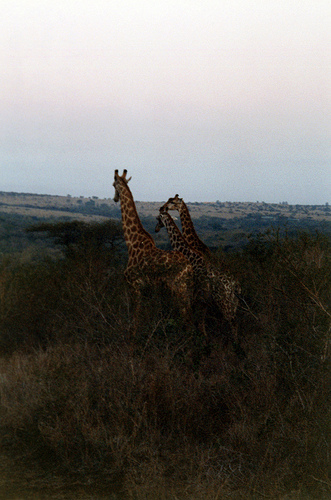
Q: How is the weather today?
A: It is clear.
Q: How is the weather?
A: It is clear.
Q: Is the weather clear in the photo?
A: Yes, it is clear.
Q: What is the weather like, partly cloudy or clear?
A: It is clear.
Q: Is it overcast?
A: No, it is clear.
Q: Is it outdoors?
A: Yes, it is outdoors.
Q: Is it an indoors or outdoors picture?
A: It is outdoors.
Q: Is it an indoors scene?
A: No, it is outdoors.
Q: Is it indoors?
A: No, it is outdoors.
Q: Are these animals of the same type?
A: Yes, all the animals are giraffes.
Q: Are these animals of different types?
A: No, all the animals are giraffes.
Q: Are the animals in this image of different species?
A: No, all the animals are giraffes.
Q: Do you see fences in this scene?
A: No, there are no fences.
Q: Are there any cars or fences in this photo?
A: No, there are no fences or cars.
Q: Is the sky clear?
A: Yes, the sky is clear.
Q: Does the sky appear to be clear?
A: Yes, the sky is clear.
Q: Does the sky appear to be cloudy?
A: No, the sky is clear.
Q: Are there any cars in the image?
A: No, there are no cars.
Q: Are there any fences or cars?
A: No, there are no cars or fences.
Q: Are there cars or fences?
A: No, there are no cars or fences.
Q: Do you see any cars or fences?
A: No, there are no cars or fences.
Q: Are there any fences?
A: No, there are no fences.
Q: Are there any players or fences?
A: No, there are no fences or players.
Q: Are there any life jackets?
A: No, there are no life jackets.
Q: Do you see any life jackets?
A: No, there are no life jackets.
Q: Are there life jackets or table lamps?
A: No, there are no life jackets or table lamps.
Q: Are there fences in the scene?
A: No, there are no fences.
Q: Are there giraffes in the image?
A: Yes, there is a giraffe.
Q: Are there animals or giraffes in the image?
A: Yes, there is a giraffe.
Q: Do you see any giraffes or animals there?
A: Yes, there is a giraffe.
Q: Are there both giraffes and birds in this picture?
A: No, there is a giraffe but no birds.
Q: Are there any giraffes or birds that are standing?
A: Yes, the giraffe is standing.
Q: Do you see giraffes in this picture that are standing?
A: Yes, there is a giraffe that is standing.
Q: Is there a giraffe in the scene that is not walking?
A: Yes, there is a giraffe that is standing.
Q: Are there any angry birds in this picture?
A: No, there are no angry birds.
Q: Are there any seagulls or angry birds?
A: No, there are no angry birds or seagulls.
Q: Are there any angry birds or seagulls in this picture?
A: No, there are no angry birds or seagulls.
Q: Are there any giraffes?
A: Yes, there is a giraffe.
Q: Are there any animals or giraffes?
A: Yes, there is a giraffe.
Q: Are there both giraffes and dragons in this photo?
A: No, there is a giraffe but no dragons.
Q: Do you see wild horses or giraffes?
A: Yes, there is a wild giraffe.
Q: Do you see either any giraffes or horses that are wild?
A: Yes, the giraffe is wild.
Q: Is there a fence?
A: No, there are no fences.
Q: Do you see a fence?
A: No, there are no fences.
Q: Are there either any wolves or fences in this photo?
A: No, there are no fences or wolves.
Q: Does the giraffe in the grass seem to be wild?
A: Yes, the giraffe is wild.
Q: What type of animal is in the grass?
A: The animal is a giraffe.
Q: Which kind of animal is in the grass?
A: The animal is a giraffe.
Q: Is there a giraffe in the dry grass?
A: Yes, there is a giraffe in the grass.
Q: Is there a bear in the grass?
A: No, there is a giraffe in the grass.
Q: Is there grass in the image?
A: Yes, there is grass.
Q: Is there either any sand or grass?
A: Yes, there is grass.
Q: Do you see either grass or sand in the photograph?
A: Yes, there is grass.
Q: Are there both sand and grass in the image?
A: No, there is grass but no sand.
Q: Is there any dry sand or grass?
A: Yes, there is dry grass.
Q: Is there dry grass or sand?
A: Yes, there is dry grass.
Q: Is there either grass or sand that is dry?
A: Yes, the grass is dry.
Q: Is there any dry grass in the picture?
A: Yes, there is dry grass.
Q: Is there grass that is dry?
A: Yes, there is grass that is dry.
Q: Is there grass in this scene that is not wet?
A: Yes, there is dry grass.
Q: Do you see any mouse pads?
A: No, there are no mouse pads.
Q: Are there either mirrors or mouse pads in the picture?
A: No, there are no mouse pads or mirrors.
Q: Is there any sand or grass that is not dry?
A: No, there is grass but it is dry.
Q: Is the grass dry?
A: Yes, the grass is dry.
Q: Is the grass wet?
A: No, the grass is dry.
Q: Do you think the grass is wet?
A: No, the grass is dry.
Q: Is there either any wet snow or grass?
A: No, there is grass but it is dry.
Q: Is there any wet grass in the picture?
A: No, there is grass but it is dry.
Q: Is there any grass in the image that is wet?
A: No, there is grass but it is dry.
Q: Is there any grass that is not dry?
A: No, there is grass but it is dry.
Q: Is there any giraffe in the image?
A: Yes, there is a giraffe.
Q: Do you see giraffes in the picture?
A: Yes, there is a giraffe.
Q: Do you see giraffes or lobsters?
A: Yes, there is a giraffe.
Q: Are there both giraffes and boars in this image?
A: No, there is a giraffe but no boars.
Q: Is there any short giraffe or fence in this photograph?
A: Yes, there is a short giraffe.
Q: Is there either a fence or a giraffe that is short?
A: Yes, the giraffe is short.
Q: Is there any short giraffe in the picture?
A: Yes, there is a short giraffe.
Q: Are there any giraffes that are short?
A: Yes, there is a giraffe that is short.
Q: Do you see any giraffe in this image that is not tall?
A: Yes, there is a short giraffe.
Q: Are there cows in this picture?
A: No, there are no cows.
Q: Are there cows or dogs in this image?
A: No, there are no cows or dogs.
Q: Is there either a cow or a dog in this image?
A: No, there are no cows or dogs.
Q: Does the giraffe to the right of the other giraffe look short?
A: Yes, the giraffe is short.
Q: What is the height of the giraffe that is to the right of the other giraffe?
A: The giraffe is short.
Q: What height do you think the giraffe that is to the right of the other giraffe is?
A: The giraffe is short.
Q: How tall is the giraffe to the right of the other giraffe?
A: The giraffe is short.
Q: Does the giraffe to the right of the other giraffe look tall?
A: No, the giraffe is short.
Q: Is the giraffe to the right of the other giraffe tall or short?
A: The giraffe is short.